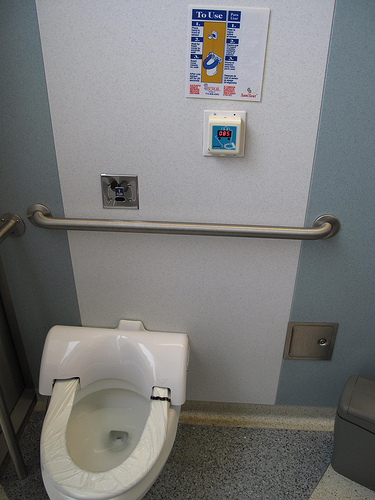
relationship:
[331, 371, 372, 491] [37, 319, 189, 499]
trash bin near toilet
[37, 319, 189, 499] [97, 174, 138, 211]
toilet has flush button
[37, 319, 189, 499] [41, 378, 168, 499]
toilet with seat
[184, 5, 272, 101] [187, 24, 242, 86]
sign with writing